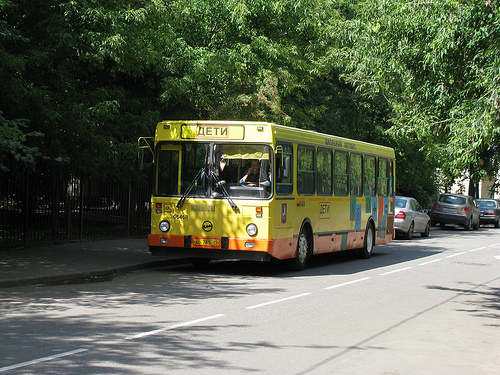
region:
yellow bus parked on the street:
[141, 117, 401, 263]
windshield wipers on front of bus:
[170, 168, 239, 213]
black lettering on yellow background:
[193, 116, 228, 136]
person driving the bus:
[229, 158, 271, 192]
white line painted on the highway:
[19, 237, 490, 373]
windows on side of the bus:
[274, 142, 391, 195]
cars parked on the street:
[396, 192, 491, 242]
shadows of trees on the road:
[5, 250, 498, 373]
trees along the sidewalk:
[13, 37, 478, 152]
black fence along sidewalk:
[1, 153, 150, 228]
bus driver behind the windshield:
[228, 145, 274, 199]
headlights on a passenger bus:
[151, 213, 268, 250]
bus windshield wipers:
[173, 141, 242, 216]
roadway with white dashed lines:
[8, 251, 498, 373]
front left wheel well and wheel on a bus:
[281, 209, 326, 272]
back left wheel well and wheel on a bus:
[354, 211, 387, 262]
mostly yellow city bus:
[129, 113, 409, 275]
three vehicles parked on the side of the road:
[394, 185, 499, 245]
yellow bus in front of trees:
[31, 0, 396, 276]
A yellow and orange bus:
[132, 112, 399, 272]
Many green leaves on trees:
[1, 2, 498, 202]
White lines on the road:
[2, 238, 499, 373]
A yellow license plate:
[189, 233, 221, 249]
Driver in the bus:
[236, 155, 273, 194]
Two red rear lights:
[429, 199, 471, 214]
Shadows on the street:
[1, 263, 498, 372]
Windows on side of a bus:
[275, 137, 392, 201]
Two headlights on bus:
[156, 216, 262, 240]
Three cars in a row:
[393, 188, 498, 239]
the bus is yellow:
[110, 88, 411, 277]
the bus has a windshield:
[146, 136, 275, 209]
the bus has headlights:
[145, 222, 277, 249]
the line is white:
[145, 294, 195, 351]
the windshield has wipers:
[178, 162, 239, 211]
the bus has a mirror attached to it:
[128, 131, 153, 173]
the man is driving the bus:
[237, 155, 271, 192]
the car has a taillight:
[393, 204, 406, 224]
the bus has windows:
[271, 135, 393, 200]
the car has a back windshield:
[437, 189, 467, 206]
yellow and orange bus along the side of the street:
[153, 120, 394, 258]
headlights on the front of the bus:
[159, 219, 263, 241]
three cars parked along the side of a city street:
[396, 193, 498, 237]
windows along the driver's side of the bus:
[274, 139, 394, 199]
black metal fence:
[12, 173, 135, 242]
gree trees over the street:
[43, 8, 461, 112]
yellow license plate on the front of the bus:
[191, 237, 221, 246]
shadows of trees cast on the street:
[13, 294, 245, 366]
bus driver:
[237, 158, 267, 188]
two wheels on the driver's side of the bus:
[295, 225, 375, 267]